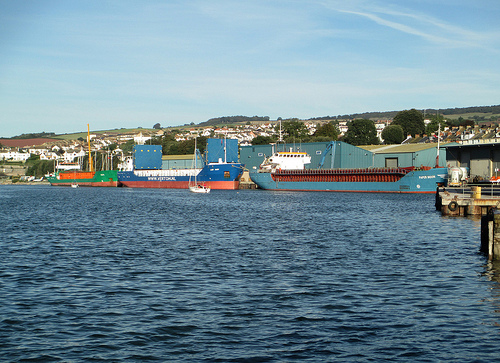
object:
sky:
[0, 0, 499, 139]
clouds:
[360, 13, 482, 58]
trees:
[290, 108, 433, 150]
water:
[0, 182, 500, 363]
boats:
[250, 148, 443, 191]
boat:
[114, 138, 243, 188]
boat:
[41, 168, 121, 186]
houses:
[24, 133, 141, 161]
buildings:
[370, 141, 445, 169]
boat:
[190, 182, 210, 194]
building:
[5, 143, 31, 162]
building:
[238, 137, 442, 170]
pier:
[435, 153, 499, 204]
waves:
[99, 210, 221, 315]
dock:
[435, 169, 494, 219]